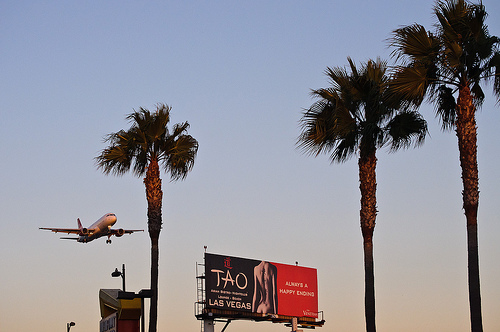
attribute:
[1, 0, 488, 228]
sky — blue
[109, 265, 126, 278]
streetlight — grey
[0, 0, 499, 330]
sky — blue , clear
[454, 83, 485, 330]
tree trunk — brown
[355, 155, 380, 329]
tree trunk — brown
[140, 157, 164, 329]
tree trunk — brown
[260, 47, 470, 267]
trees — palm, three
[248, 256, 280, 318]
person — naked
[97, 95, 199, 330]
palm tree — tall